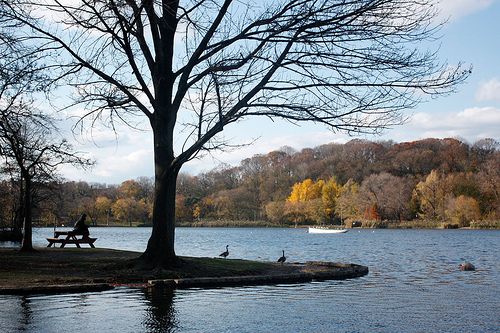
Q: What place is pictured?
A: It is a forest.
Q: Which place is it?
A: It is a forest.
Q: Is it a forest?
A: Yes, it is a forest.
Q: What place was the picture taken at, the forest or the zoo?
A: It was taken at the forest.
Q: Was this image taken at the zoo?
A: No, the picture was taken in the forest.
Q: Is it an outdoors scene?
A: Yes, it is outdoors.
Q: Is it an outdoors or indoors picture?
A: It is outdoors.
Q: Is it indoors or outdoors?
A: It is outdoors.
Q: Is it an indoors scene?
A: No, it is outdoors.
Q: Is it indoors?
A: No, it is outdoors.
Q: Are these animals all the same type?
A: Yes, all the animals are birds.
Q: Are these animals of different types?
A: No, all the animals are birds.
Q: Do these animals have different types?
A: No, all the animals are birds.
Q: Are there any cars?
A: No, there are no cars.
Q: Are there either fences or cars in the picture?
A: No, there are no cars or fences.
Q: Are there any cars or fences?
A: No, there are no cars or fences.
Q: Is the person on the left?
A: Yes, the person is on the left of the image.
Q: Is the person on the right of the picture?
A: No, the person is on the left of the image.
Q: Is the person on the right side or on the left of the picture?
A: The person is on the left of the image.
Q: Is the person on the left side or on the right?
A: The person is on the left of the image.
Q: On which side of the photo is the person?
A: The person is on the left of the image.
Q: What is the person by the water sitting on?
A: The person is sitting on the table.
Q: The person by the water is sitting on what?
A: The person is sitting on the table.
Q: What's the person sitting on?
A: The person is sitting on the table.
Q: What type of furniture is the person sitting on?
A: The person is sitting on the table.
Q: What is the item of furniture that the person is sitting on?
A: The piece of furniture is a table.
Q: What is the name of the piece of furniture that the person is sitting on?
A: The piece of furniture is a table.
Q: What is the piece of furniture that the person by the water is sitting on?
A: The piece of furniture is a table.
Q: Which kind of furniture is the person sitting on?
A: The person is sitting on the table.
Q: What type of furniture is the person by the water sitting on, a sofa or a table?
A: The person is sitting on a table.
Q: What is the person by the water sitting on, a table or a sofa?
A: The person is sitting on a table.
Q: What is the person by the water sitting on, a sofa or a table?
A: The person is sitting on a table.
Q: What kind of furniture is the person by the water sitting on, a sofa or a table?
A: The person is sitting on a table.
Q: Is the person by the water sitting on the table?
A: Yes, the person is sitting on the table.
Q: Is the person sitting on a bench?
A: No, the person is sitting on the table.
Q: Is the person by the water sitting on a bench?
A: No, the person is sitting on the table.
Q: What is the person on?
A: The person is on the table.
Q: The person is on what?
A: The person is on the table.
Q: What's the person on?
A: The person is on the table.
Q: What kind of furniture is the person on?
A: The person is on the table.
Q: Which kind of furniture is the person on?
A: The person is on the table.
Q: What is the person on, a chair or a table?
A: The person is on a table.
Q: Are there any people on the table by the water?
A: Yes, there is a person on the table.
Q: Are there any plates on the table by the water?
A: No, there is a person on the table.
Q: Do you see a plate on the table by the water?
A: No, there is a person on the table.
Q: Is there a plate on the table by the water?
A: No, there is a person on the table.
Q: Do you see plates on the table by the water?
A: No, there is a person on the table.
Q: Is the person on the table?
A: Yes, the person is on the table.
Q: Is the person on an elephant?
A: No, the person is on the table.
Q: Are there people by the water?
A: Yes, there is a person by the water.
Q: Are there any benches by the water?
A: No, there is a person by the water.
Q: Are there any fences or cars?
A: No, there are no cars or fences.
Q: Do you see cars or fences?
A: No, there are no cars or fences.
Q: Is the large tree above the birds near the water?
A: Yes, the tree is above the birds.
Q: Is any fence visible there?
A: No, there are no fences.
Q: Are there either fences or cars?
A: No, there are no fences or cars.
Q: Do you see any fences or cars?
A: No, there are no fences or cars.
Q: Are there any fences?
A: No, there are no fences.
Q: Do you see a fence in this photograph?
A: No, there are no fences.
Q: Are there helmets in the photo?
A: No, there are no helmets.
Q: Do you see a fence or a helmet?
A: No, there are no helmets or fences.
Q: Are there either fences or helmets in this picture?
A: No, there are no helmets or fences.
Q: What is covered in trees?
A: The hill is covered in trees.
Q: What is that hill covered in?
A: The hill is covered in trees.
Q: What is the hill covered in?
A: The hill is covered in trees.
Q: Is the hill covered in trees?
A: Yes, the hill is covered in trees.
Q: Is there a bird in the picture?
A: Yes, there are birds.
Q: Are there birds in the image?
A: Yes, there are birds.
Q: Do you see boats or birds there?
A: Yes, there are birds.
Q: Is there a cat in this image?
A: No, there are no cats.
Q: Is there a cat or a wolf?
A: No, there are no cats or wolves.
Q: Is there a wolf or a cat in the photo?
A: No, there are no cats or wolves.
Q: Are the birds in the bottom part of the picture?
A: Yes, the birds are in the bottom of the image.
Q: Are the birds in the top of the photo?
A: No, the birds are in the bottom of the image.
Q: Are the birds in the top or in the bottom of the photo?
A: The birds are in the bottom of the image.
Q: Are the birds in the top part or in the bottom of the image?
A: The birds are in the bottom of the image.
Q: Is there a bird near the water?
A: Yes, there are birds near the water.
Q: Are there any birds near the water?
A: Yes, there are birds near the water.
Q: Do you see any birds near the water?
A: Yes, there are birds near the water.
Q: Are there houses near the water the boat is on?
A: No, there are birds near the water.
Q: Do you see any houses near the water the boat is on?
A: No, there are birds near the water.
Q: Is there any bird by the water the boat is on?
A: Yes, there are birds by the water.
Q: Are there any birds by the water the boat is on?
A: Yes, there are birds by the water.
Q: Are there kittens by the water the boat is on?
A: No, there are birds by the water.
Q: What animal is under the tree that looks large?
A: The birds are under the tree.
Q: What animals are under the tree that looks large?
A: The animals are birds.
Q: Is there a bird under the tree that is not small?
A: Yes, there are birds under the tree.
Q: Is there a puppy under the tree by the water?
A: No, there are birds under the tree.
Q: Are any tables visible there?
A: Yes, there is a table.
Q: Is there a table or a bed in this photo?
A: Yes, there is a table.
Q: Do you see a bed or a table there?
A: Yes, there is a table.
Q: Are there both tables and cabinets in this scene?
A: No, there is a table but no cabinets.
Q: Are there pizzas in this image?
A: No, there are no pizzas.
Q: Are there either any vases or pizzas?
A: No, there are no pizzas or vases.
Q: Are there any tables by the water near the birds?
A: Yes, there is a table by the water.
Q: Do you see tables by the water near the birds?
A: Yes, there is a table by the water.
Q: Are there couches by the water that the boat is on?
A: No, there is a table by the water.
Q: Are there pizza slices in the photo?
A: No, there are no pizza slices.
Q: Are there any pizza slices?
A: No, there are no pizza slices.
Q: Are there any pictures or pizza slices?
A: No, there are no pizza slices or pictures.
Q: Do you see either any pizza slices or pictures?
A: No, there are no pizza slices or pictures.